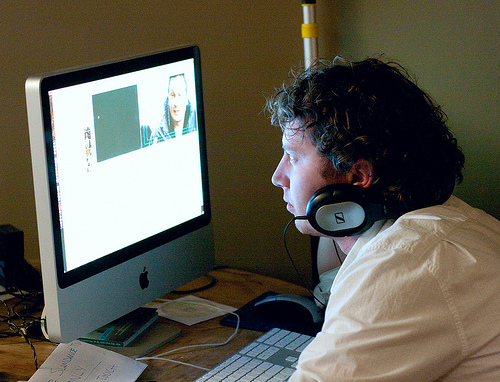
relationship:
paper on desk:
[28, 325, 155, 381] [34, 217, 374, 380]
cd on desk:
[148, 285, 247, 335] [24, 226, 365, 379]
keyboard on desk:
[178, 314, 327, 381] [42, 236, 372, 380]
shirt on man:
[246, 222, 497, 381] [249, 52, 496, 381]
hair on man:
[224, 25, 490, 236] [200, 40, 483, 379]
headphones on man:
[302, 196, 392, 243] [261, 17, 498, 380]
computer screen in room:
[35, 44, 209, 350] [2, 4, 498, 379]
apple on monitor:
[129, 263, 161, 303] [14, 43, 224, 313]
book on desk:
[50, 294, 173, 354] [9, 233, 383, 378]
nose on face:
[256, 156, 299, 212] [252, 57, 445, 264]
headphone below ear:
[257, 188, 401, 278] [312, 130, 383, 202]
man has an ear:
[257, 51, 500, 381] [312, 130, 383, 202]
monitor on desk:
[17, 26, 209, 357] [7, 237, 417, 378]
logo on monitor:
[125, 263, 166, 303] [38, 33, 212, 364]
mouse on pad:
[249, 283, 311, 313] [226, 289, 311, 322]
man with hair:
[257, 51, 500, 381] [287, 92, 422, 144]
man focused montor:
[246, 60, 474, 360] [15, 51, 255, 348]